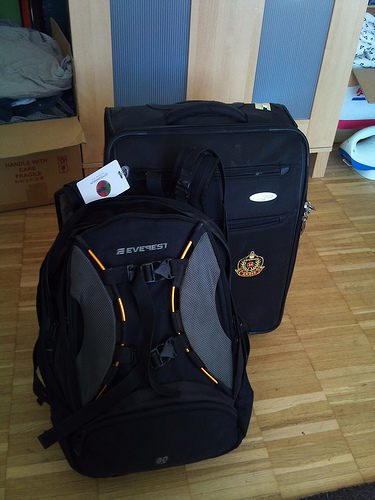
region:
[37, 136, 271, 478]
this is a backpack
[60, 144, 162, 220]
this is a white tag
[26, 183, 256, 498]
the backpack is black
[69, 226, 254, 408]
grey panels on backpack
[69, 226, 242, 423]
orange trim on backpack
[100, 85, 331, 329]
this is a suitcase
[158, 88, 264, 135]
black handle on suitcase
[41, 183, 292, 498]
backpack sitting on the floor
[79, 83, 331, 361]
suitcase sitting on the floor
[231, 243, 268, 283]
golden crest on suitcase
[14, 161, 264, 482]
black backpack with yellow and grey accents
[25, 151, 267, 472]
black backpack with luggage tag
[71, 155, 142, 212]
luggage tag on black backpack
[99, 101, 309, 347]
black suitcase with gold emblem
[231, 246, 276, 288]
gold emblem on suitcase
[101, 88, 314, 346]
black rolling suitcase with zippers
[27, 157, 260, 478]
black backpack with zippered pockets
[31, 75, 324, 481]
backpack and suitcase sitting on floor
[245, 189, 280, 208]
oval decal on black suitcase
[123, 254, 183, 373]
black plastic buckles on backpack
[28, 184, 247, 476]
this is a back pack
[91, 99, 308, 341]
this is a suit case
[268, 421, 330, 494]
this is a wooden floor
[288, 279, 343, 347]
this is a wooden floor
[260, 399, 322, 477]
this is a wooden floor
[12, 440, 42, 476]
this is a wooden floor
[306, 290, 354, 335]
this is a wooden floor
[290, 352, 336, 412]
this is a wooden floor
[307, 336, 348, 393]
this is a wooden floor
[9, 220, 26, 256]
this is a wooden floor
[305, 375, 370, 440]
part of the hardwood floor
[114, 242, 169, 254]
name of luggage maker on bag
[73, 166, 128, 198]
a tag on the dark bag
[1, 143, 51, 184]
red writing on cardboard box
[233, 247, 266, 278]
a logo on the dark luggage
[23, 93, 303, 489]
several pieces of luggage on floor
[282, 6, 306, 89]
part of the wall behind luggage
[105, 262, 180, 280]
a strap on the luggage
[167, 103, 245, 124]
handle on the dark luggage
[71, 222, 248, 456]
black and orange backpack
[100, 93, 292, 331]
luggage next to backpack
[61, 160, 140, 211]
white tag on backpack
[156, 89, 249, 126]
black handle on luggage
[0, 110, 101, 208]
brown cardboard box on floor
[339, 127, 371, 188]
white tool on floor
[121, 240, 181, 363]
black snaps on backpack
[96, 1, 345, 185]
brown and blue closet